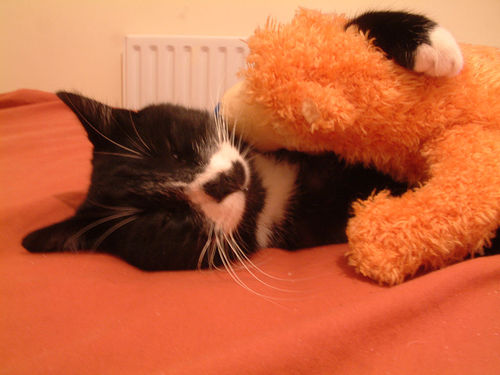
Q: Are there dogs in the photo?
A: No, there are no dogs.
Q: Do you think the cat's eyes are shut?
A: Yes, the eyes are shut.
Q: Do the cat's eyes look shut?
A: Yes, the eyes are shut.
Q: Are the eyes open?
A: No, the eyes are shut.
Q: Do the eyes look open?
A: No, the eyes are shut.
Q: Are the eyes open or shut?
A: The eyes are shut.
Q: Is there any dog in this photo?
A: No, there are no dogs.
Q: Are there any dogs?
A: No, there are no dogs.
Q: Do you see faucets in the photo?
A: No, there are no faucets.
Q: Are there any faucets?
A: No, there are no faucets.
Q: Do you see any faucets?
A: No, there are no faucets.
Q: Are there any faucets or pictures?
A: No, there are no faucets or pictures.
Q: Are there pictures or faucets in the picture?
A: No, there are no faucets or pictures.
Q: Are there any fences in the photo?
A: No, there are no fences.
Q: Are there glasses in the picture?
A: No, there are no glasses.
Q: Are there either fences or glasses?
A: No, there are no glasses or fences.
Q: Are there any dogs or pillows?
A: No, there are no dogs or pillows.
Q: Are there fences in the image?
A: No, there are no fences.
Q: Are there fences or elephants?
A: No, there are no fences or elephants.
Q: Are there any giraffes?
A: No, there are no giraffes.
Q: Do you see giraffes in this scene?
A: No, there are no giraffes.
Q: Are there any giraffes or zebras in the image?
A: No, there are no giraffes or zebras.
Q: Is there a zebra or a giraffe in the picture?
A: No, there are no giraffes or zebras.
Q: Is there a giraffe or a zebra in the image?
A: No, there are no giraffes or zebras.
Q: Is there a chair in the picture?
A: No, there are no chairs.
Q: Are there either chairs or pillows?
A: No, there are no chairs or pillows.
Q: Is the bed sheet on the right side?
A: No, the bed sheet is on the left of the image.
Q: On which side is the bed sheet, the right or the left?
A: The bed sheet is on the left of the image.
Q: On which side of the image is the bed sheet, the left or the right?
A: The bed sheet is on the left of the image.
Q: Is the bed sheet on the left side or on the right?
A: The bed sheet is on the left of the image.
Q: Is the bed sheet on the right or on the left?
A: The bed sheet is on the left of the image.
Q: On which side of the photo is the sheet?
A: The sheet is on the left of the image.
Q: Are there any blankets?
A: Yes, there is a blanket.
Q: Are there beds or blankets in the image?
A: Yes, there is a blanket.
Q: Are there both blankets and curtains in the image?
A: No, there is a blanket but no curtains.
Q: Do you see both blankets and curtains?
A: No, there is a blanket but no curtains.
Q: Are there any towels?
A: No, there are no towels.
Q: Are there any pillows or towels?
A: No, there are no towels or pillows.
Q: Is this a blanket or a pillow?
A: This is a blanket.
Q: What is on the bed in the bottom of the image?
A: The blanket is on the bed.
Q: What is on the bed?
A: The blanket is on the bed.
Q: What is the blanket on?
A: The blanket is on the bed.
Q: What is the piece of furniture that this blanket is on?
A: The piece of furniture is a bed.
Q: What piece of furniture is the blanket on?
A: The blanket is on the bed.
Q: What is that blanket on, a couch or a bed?
A: The blanket is on a bed.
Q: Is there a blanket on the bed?
A: Yes, there is a blanket on the bed.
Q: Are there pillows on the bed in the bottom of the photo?
A: No, there is a blanket on the bed.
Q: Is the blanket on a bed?
A: Yes, the blanket is on a bed.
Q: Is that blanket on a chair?
A: No, the blanket is on a bed.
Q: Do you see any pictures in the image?
A: No, there are no pictures.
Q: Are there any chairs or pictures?
A: No, there are no pictures or chairs.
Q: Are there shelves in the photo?
A: No, there are no shelves.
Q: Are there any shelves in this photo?
A: No, there are no shelves.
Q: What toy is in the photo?
A: The toy is a stuffed animal.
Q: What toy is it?
A: The toy is a stuffed animal.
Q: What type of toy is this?
A: That is a stuffed animal.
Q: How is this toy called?
A: That is a stuffed animal.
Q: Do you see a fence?
A: No, there are no fences.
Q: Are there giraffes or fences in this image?
A: No, there are no fences or giraffes.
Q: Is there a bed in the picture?
A: Yes, there is a bed.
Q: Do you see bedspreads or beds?
A: Yes, there is a bed.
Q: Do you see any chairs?
A: No, there are no chairs.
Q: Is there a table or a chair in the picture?
A: No, there are no chairs or tables.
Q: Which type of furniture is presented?
A: The furniture is a bed.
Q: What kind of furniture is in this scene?
A: The furniture is a bed.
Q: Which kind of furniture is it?
A: The piece of furniture is a bed.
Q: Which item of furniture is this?
A: This is a bed.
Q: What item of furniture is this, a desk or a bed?
A: This is a bed.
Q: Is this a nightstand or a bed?
A: This is a bed.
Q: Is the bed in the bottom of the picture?
A: Yes, the bed is in the bottom of the image.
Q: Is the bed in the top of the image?
A: No, the bed is in the bottom of the image.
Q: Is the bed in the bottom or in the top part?
A: The bed is in the bottom of the image.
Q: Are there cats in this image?
A: Yes, there is a cat.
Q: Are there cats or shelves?
A: Yes, there is a cat.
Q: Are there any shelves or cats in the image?
A: Yes, there is a cat.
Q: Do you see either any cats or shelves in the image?
A: Yes, there is a cat.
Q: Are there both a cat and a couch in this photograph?
A: No, there is a cat but no couches.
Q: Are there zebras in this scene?
A: No, there are no zebras.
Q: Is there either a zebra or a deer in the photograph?
A: No, there are no zebras or deer.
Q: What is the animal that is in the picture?
A: The animal is a cat.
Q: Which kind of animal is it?
A: The animal is a cat.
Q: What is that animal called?
A: This is a cat.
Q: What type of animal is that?
A: This is a cat.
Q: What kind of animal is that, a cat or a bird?
A: This is a cat.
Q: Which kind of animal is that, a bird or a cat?
A: This is a cat.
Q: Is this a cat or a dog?
A: This is a cat.